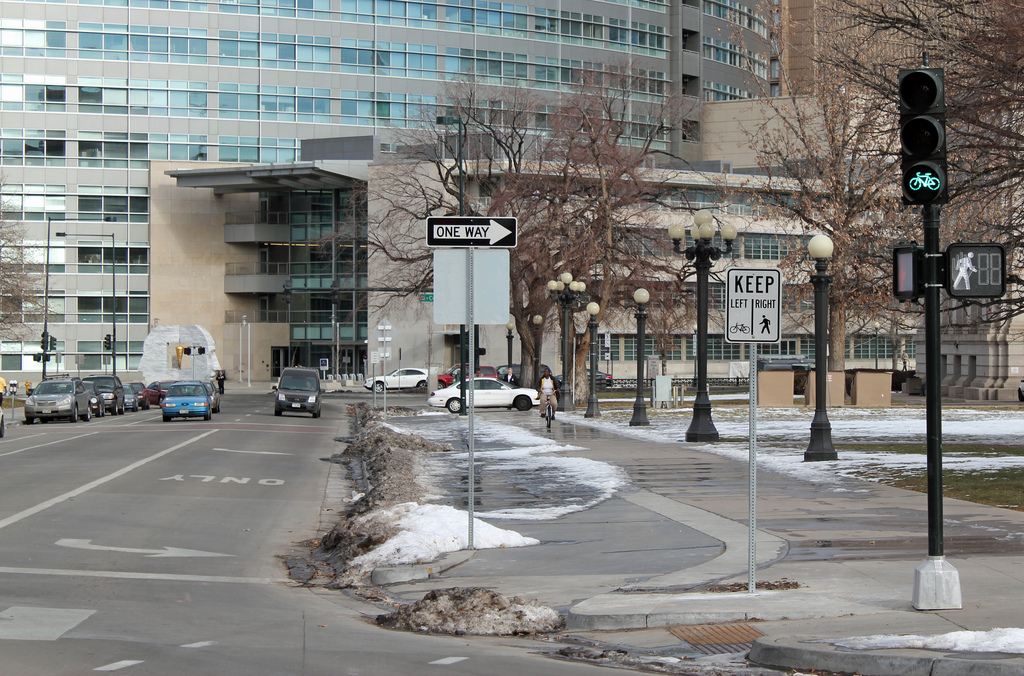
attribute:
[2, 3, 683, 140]
window panes — rows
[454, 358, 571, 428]
bicyclist — white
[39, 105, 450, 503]
building — large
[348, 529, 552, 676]
snow — slush,dirty and melting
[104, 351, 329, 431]
cars — moving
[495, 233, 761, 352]
globes — white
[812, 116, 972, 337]
bicycle — green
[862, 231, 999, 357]
walking figure — white